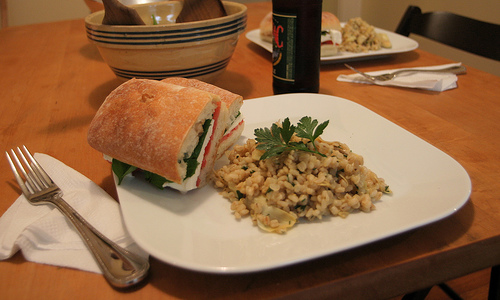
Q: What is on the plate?
A: A sandwich and rice.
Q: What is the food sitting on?
A: A plate.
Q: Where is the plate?
A: On a table.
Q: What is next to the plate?
A: A fork.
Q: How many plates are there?
A: One.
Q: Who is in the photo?
A: Nobody.